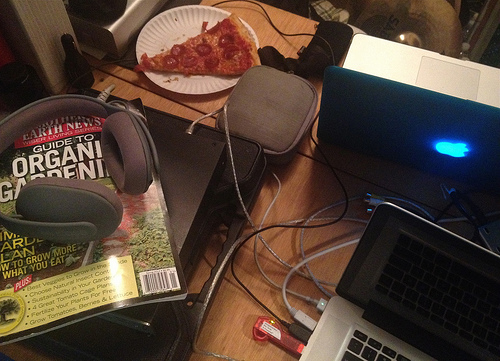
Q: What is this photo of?
A: A desktop.